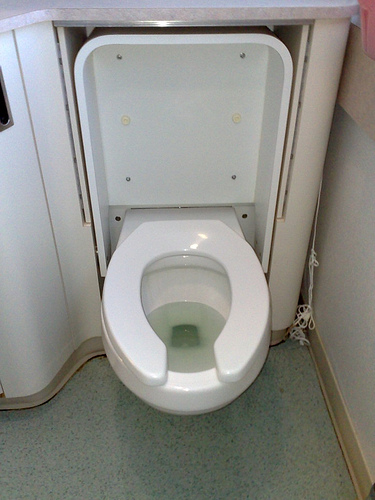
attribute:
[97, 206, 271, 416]
toilet — white, porcelain, clean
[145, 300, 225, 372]
water — clear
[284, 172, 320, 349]
cord — hanging, white, hanging down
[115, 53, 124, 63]
bolt — silver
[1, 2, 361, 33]
countertop — white, marble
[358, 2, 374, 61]
container — red, plastic, pink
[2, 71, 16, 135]
hole — metal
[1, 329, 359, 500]
floor — speckled, dirty, dotted, blue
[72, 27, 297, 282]
toilet structure — white, metal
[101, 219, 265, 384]
toilet seat — white, plastic, down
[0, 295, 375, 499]
molding — cream, tan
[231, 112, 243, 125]
screw — white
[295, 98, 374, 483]
wall — white